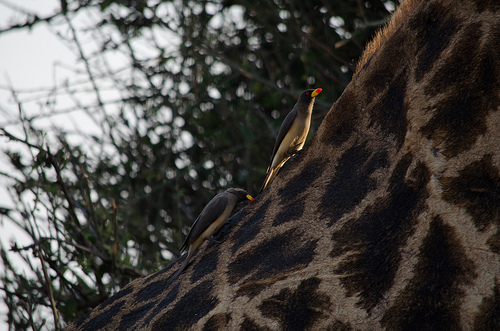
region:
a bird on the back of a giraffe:
[187, 180, 250, 252]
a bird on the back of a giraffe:
[265, 85, 321, 174]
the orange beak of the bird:
[244, 192, 253, 202]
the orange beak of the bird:
[312, 85, 322, 95]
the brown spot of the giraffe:
[382, 213, 470, 323]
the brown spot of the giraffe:
[253, 278, 333, 329]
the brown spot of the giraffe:
[230, 231, 315, 288]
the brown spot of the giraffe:
[145, 276, 218, 326]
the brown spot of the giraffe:
[240, 309, 265, 329]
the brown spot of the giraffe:
[202, 310, 234, 330]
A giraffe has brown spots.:
[66, 1, 499, 328]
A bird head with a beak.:
[297, 87, 322, 98]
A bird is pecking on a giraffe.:
[163, 185, 256, 274]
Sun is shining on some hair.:
[350, 2, 412, 81]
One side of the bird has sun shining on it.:
[256, 83, 326, 195]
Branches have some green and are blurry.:
[1, 0, 400, 330]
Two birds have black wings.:
[166, 89, 322, 278]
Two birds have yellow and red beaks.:
[171, 85, 322, 285]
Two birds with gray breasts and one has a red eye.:
[177, 86, 324, 278]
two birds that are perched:
[158, 70, 346, 266]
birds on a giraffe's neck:
[158, 73, 363, 270]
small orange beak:
[313, 83, 323, 93]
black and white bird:
[173, 177, 268, 249]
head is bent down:
[233, 186, 255, 204]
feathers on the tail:
[260, 158, 280, 197]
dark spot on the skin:
[218, 220, 323, 308]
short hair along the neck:
[331, 0, 421, 83]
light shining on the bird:
[298, 101, 313, 148]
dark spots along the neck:
[49, 0, 499, 328]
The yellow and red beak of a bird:
[311, 86, 321, 96]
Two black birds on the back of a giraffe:
[160, 83, 322, 270]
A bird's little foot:
[210, 236, 230, 243]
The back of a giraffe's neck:
[74, 12, 499, 329]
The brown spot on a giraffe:
[227, 227, 317, 290]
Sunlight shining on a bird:
[272, 84, 326, 176]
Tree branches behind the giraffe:
[10, 0, 362, 322]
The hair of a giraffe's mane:
[346, 0, 422, 69]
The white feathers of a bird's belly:
[281, 115, 311, 161]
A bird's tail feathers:
[165, 247, 200, 282]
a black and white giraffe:
[17, 19, 498, 329]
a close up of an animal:
[5, 8, 495, 323]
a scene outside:
[12, 11, 484, 326]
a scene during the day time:
[12, 18, 477, 326]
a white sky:
[6, 3, 168, 177]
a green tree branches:
[5, 8, 329, 242]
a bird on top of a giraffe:
[240, 38, 361, 202]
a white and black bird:
[242, 65, 360, 205]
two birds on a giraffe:
[155, 78, 389, 265]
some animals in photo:
[17, 9, 458, 326]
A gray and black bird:
[170, 183, 252, 250]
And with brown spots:
[263, 201, 380, 271]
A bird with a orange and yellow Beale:
[243, 177, 268, 211]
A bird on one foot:
[241, 120, 316, 202]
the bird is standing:
[261, 86, 321, 190]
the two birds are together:
[166, 88, 322, 283]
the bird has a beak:
[167, 187, 257, 284]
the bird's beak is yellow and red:
[256, 85, 323, 190]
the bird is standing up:
[263, 87, 322, 192]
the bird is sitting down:
[143, 185, 256, 285]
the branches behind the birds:
[1, 0, 403, 328]